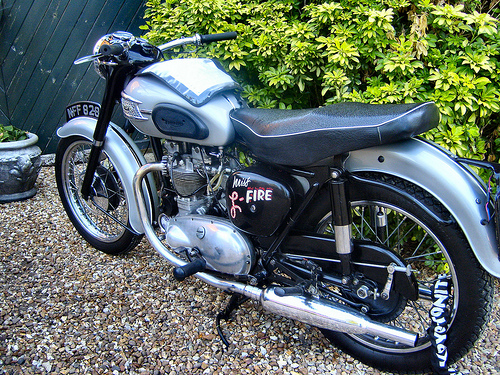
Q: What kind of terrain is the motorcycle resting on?
A: Gravel.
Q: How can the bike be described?
A: A black and silver bike.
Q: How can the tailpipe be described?
A: Chrome.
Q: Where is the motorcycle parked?
A: A gravel driveway.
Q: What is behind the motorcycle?
A: Green plants.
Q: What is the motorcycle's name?
A: L-Fire.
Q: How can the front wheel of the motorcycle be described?
A: A front wheel with spokes.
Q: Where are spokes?
A: On wheel.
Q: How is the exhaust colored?
A: Silver.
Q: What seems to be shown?
A: Motorcycle.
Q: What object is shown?
A: Motorbike.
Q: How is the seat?
A: Leather like.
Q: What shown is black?
A: The wheel.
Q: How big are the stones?
A: Small.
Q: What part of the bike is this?
A: Back seat.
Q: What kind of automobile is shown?
A: A motorcycle?.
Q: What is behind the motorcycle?
A: Green bushes.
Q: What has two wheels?
A: The motorcycle.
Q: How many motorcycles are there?
A: 1.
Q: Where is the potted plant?
A: On the ground.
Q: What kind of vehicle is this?
A: Motorcycle.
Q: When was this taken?
A: Daytime.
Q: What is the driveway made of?
A: Gravel.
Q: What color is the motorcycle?
A: Silver.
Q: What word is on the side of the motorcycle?
A: Fire.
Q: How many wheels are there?
A: 2.